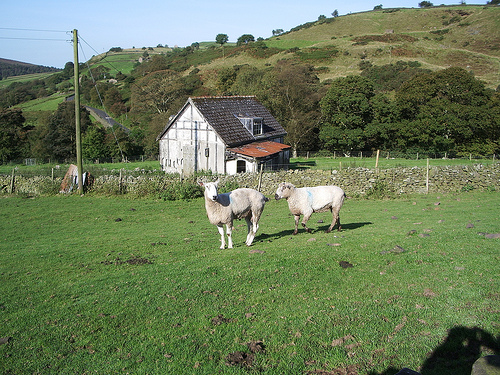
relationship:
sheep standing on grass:
[201, 175, 267, 248] [1, 158, 498, 373]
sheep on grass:
[265, 175, 354, 231] [1, 158, 498, 373]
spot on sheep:
[299, 182, 324, 214] [270, 169, 345, 238]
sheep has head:
[196, 178, 268, 250] [199, 180, 214, 201]